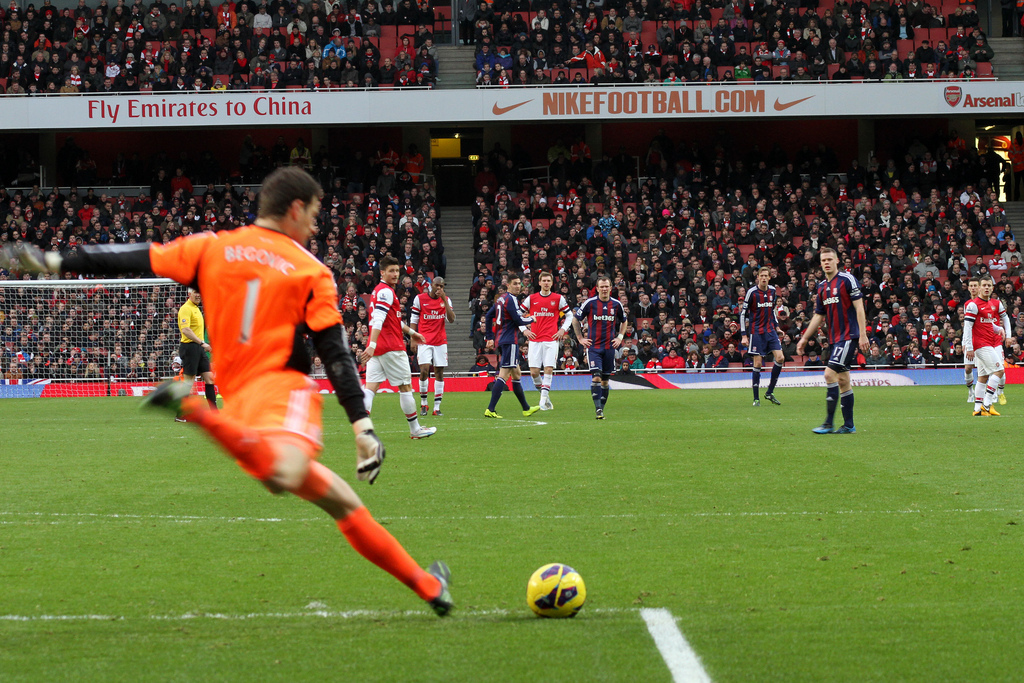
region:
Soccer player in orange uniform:
[35, 164, 457, 618]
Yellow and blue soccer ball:
[525, 557, 587, 616]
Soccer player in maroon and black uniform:
[792, 241, 876, 435]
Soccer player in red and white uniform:
[511, 271, 581, 417]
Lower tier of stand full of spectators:
[5, 126, 1021, 380]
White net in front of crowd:
[2, 277, 214, 382]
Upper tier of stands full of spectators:
[3, 0, 1022, 131]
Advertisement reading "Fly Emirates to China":
[84, 92, 319, 127]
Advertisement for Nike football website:
[487, 82, 817, 118]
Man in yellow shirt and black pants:
[174, 288, 219, 410]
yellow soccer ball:
[520, 562, 588, 619]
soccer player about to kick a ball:
[0, 167, 454, 617]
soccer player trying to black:
[577, 278, 634, 421]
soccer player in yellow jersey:
[174, 282, 223, 412]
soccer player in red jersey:
[519, 272, 574, 413]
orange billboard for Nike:
[490, 85, 817, 118]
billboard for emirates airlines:
[84, 97, 310, 123]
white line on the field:
[637, 603, 711, 680]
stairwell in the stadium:
[437, 205, 480, 376]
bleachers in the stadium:
[2, 4, 1021, 397]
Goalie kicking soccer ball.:
[8, 156, 594, 622]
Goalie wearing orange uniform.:
[3, 151, 465, 617]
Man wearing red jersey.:
[363, 249, 433, 440]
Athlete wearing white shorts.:
[524, 268, 559, 405]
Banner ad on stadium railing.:
[470, 87, 816, 119]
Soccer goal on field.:
[3, 260, 188, 432]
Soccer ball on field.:
[523, 560, 587, 624]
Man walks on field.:
[359, 249, 435, 442]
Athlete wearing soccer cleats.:
[809, 359, 866, 440]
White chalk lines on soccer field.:
[0, 494, 323, 646]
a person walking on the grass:
[40, 158, 484, 640]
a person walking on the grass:
[793, 241, 885, 425]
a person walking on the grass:
[956, 278, 1001, 389]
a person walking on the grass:
[581, 256, 623, 421]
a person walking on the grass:
[515, 267, 563, 410]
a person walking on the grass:
[413, 272, 459, 413]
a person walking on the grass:
[353, 247, 436, 434]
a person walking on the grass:
[158, 270, 220, 419]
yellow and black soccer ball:
[527, 560, 585, 615]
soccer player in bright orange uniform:
[21, 164, 455, 617]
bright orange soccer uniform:
[150, 224, 442, 597]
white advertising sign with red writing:
[1, 86, 1020, 129]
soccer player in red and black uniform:
[483, 270, 531, 416]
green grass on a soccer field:
[5, 382, 1021, 680]